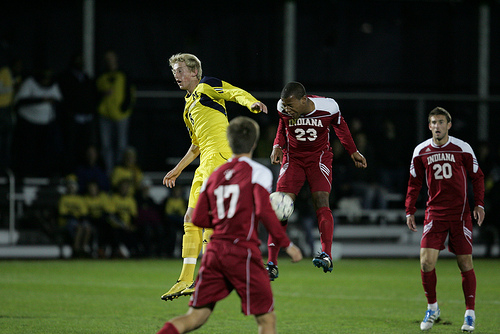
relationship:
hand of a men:
[157, 167, 183, 192] [158, 50, 271, 302]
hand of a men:
[245, 104, 268, 119] [158, 50, 271, 302]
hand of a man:
[348, 149, 367, 168] [262, 78, 371, 283]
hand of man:
[348, 149, 367, 168] [262, 78, 371, 283]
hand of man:
[268, 148, 284, 167] [262, 78, 371, 283]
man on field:
[396, 107, 488, 322] [4, 233, 500, 329]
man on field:
[176, 116, 308, 333] [4, 233, 500, 329]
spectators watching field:
[12, 38, 498, 278] [4, 233, 500, 329]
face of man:
[430, 107, 449, 140] [396, 107, 488, 322]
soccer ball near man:
[270, 189, 298, 225] [262, 78, 371, 283]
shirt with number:
[265, 96, 360, 159] [294, 126, 319, 146]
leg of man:
[311, 187, 339, 271] [262, 78, 371, 283]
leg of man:
[262, 160, 300, 270] [262, 78, 371, 283]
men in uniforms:
[185, 79, 488, 333] [189, 101, 486, 315]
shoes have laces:
[418, 306, 481, 332] [422, 309, 475, 324]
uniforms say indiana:
[189, 101, 486, 315] [287, 116, 463, 166]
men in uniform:
[158, 50, 271, 302] [174, 80, 252, 210]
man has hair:
[396, 107, 488, 322] [425, 109, 456, 123]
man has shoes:
[396, 107, 488, 322] [418, 306, 481, 332]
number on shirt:
[211, 183, 243, 224] [192, 160, 272, 243]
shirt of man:
[192, 160, 272, 243] [176, 116, 308, 333]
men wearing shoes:
[158, 50, 271, 302] [157, 275, 204, 300]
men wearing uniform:
[158, 50, 271, 302] [174, 80, 252, 210]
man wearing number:
[176, 116, 308, 333] [211, 183, 243, 224]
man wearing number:
[262, 78, 371, 283] [294, 126, 319, 146]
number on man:
[211, 183, 243, 224] [176, 116, 308, 333]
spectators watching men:
[12, 38, 498, 278] [185, 79, 488, 333]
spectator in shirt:
[15, 65, 66, 179] [22, 81, 58, 124]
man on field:
[262, 78, 371, 283] [4, 233, 500, 329]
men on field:
[158, 50, 271, 302] [4, 233, 500, 329]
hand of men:
[157, 167, 183, 192] [158, 50, 271, 302]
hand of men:
[245, 104, 268, 119] [158, 50, 271, 302]